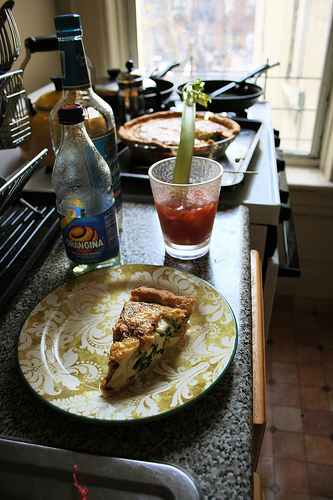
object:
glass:
[149, 161, 221, 254]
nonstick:
[119, 55, 278, 104]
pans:
[108, 60, 287, 156]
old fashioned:
[19, 38, 99, 167]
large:
[128, 0, 330, 174]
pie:
[119, 104, 239, 156]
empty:
[52, 108, 122, 268]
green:
[19, 266, 235, 421]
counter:
[0, 199, 252, 499]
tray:
[119, 112, 237, 169]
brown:
[251, 299, 330, 498]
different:
[270, 299, 329, 494]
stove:
[24, 86, 286, 228]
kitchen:
[6, 3, 329, 497]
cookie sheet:
[105, 118, 262, 190]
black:
[182, 54, 281, 110]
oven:
[83, 100, 300, 363]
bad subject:
[198, 26, 295, 107]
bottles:
[48, 102, 124, 271]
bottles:
[48, 9, 123, 266]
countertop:
[10, 187, 258, 416]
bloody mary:
[146, 78, 224, 262]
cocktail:
[143, 77, 221, 259]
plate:
[13, 259, 244, 428]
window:
[135, 0, 331, 154]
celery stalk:
[172, 79, 210, 184]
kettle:
[20, 33, 110, 162]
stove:
[2, 61, 306, 369]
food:
[87, 82, 243, 397]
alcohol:
[54, 96, 122, 234]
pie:
[102, 285, 197, 392]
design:
[17, 263, 237, 422]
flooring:
[259, 293, 331, 498]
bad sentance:
[171, 225, 325, 313]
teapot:
[6, 30, 102, 155]